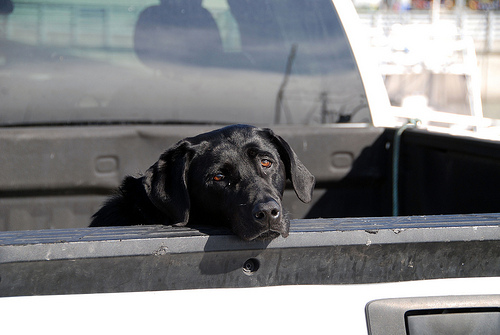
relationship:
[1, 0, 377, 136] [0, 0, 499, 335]
window in pickup truck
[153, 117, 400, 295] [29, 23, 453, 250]
dog back of truck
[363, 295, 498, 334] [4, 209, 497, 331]
handle to tailgate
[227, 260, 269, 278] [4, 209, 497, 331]
screw in tailgate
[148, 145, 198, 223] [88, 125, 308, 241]
ear of dog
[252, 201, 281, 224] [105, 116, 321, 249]
nose of dog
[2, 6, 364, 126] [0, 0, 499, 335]
back window of a pickup truck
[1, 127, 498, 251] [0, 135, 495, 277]
bed of a pickup truck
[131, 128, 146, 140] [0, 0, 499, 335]
dent in bed of a pickup truck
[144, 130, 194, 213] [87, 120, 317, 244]
ear of dog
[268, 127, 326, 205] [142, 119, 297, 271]
ear of dog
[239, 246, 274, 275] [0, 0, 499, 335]
key hole in pickup truck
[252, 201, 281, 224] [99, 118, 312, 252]
nose of dog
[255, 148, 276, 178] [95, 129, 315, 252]
eye on dog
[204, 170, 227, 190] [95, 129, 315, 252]
eye on dog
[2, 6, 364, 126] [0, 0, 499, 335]
back window of pickup truck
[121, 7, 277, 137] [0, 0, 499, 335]
seat in pickup truck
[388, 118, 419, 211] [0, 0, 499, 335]
rope on pickup truck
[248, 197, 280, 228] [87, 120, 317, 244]
nose on dog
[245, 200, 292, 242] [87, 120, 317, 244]
muzzle of dog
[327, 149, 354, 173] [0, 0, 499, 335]
knob inside a pickup truck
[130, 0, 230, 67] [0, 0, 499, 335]
head rest inside a pickup truck